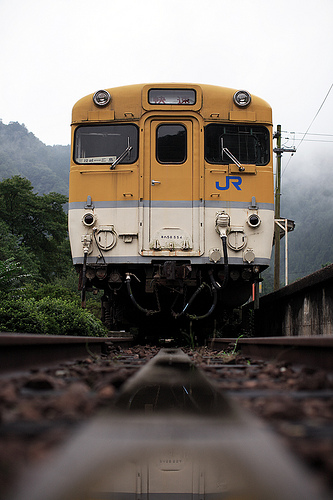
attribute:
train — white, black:
[70, 83, 278, 338]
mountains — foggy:
[2, 121, 332, 201]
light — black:
[249, 213, 260, 231]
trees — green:
[2, 174, 107, 336]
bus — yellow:
[71, 83, 277, 336]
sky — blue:
[2, 6, 331, 173]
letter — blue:
[218, 177, 243, 192]